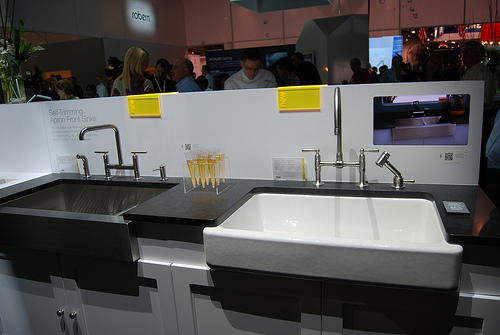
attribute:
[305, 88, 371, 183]
tap — clear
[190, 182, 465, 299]
sink — white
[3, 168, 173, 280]
sink — black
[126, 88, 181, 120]
markers — yellow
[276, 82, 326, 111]
markers — yellow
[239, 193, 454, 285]
sink — white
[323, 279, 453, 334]
cabinet — white, lower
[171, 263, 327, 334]
cabinet — lower, white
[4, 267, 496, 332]
cabinets — white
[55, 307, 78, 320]
hardware — chrome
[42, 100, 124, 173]
sign — white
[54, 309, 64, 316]
nob — silver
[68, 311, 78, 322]
nob — silver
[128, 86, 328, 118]
post — yellow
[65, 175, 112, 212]
water tap — clear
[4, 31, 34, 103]
plant — green